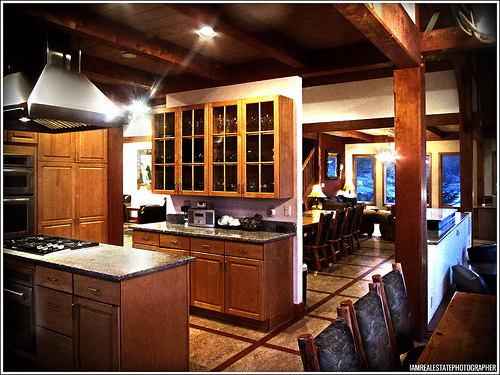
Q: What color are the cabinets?
A: Brown.